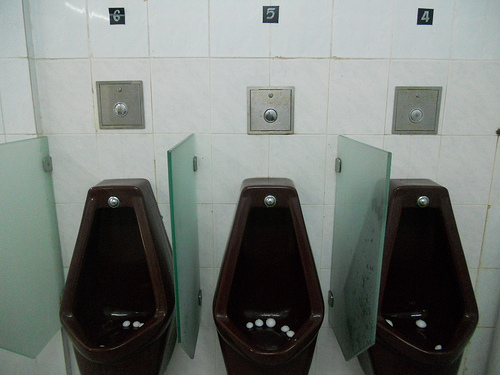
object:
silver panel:
[247, 86, 295, 133]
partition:
[326, 135, 394, 362]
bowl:
[58, 179, 173, 375]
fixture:
[249, 87, 295, 134]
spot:
[495, 128, 499, 137]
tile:
[149, 57, 215, 134]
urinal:
[360, 177, 478, 375]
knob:
[416, 197, 430, 208]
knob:
[107, 197, 119, 208]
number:
[421, 10, 431, 23]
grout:
[220, 56, 351, 60]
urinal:
[210, 177, 323, 375]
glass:
[326, 135, 391, 364]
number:
[267, 8, 275, 19]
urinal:
[59, 178, 176, 375]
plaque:
[108, 7, 125, 26]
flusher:
[264, 109, 276, 122]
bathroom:
[0, 0, 500, 375]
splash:
[349, 228, 377, 353]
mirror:
[1, 0, 36, 137]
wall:
[0, 2, 500, 375]